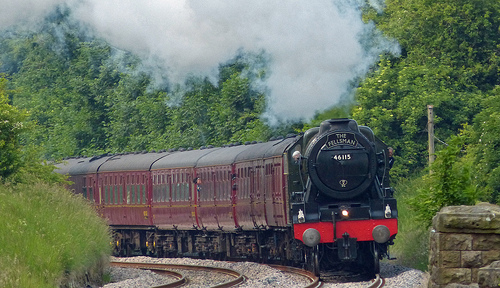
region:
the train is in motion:
[1, 82, 406, 282]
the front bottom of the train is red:
[285, 205, 410, 261]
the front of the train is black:
[270, 104, 403, 206]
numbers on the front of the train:
[319, 142, 359, 167]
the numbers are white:
[322, 145, 367, 167]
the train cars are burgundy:
[29, 122, 305, 247]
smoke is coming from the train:
[47, 0, 393, 122]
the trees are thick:
[0, 5, 480, 196]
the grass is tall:
[0, 186, 122, 281]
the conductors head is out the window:
[168, 168, 242, 197]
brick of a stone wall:
[437, 235, 468, 249]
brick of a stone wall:
[471, 238, 496, 250]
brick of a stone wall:
[482, 253, 498, 270]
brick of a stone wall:
[458, 248, 479, 265]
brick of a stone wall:
[437, 250, 459, 265]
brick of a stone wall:
[441, 267, 471, 281]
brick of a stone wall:
[477, 270, 496, 283]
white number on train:
[331, 153, 337, 162]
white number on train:
[336, 153, 341, 161]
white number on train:
[346, 150, 353, 162]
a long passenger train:
[43, 114, 398, 283]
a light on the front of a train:
[338, 206, 351, 218]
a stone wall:
[427, 212, 499, 287]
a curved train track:
[105, 253, 247, 286]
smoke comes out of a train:
[0, 2, 397, 124]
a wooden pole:
[422, 102, 439, 175]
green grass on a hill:
[1, 188, 114, 286]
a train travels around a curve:
[53, 115, 398, 279]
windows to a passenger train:
[76, 162, 259, 209]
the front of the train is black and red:
[283, 117, 404, 279]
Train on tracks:
[5, 106, 408, 269]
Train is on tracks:
[30, 110, 406, 275]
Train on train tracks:
[32, 110, 412, 280]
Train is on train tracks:
[35, 115, 400, 276]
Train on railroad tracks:
[36, 111, 407, 277]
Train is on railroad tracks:
[35, 105, 400, 280]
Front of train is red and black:
[292, 108, 405, 262]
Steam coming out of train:
[0, 1, 417, 131]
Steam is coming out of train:
[2, 0, 411, 138]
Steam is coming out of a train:
[0, 2, 421, 145]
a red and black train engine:
[285, 114, 393, 285]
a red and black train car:
[233, 133, 301, 246]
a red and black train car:
[148, 145, 203, 262]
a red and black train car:
[99, 151, 159, 253]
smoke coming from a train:
[37, 0, 405, 132]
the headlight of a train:
[339, 207, 352, 224]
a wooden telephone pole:
[418, 101, 443, 190]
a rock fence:
[421, 204, 498, 284]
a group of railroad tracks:
[125, 255, 382, 287]